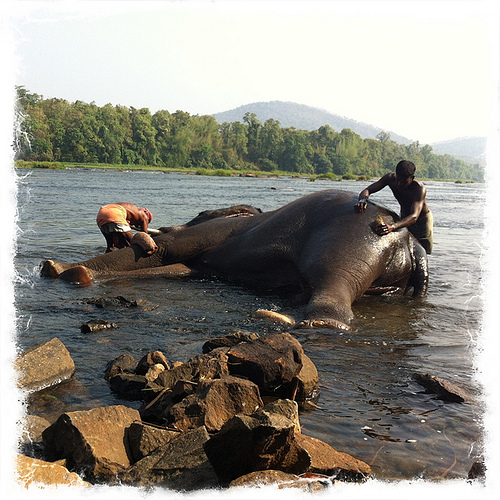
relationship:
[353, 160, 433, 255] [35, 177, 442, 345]
man washing elephant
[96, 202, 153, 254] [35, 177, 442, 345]
man washing elephant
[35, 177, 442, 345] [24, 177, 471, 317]
elephant in water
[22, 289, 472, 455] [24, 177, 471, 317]
rocks in water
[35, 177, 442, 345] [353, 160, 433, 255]
elephant by man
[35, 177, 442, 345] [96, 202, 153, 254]
elephant by man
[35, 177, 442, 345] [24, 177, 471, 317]
elephant laying in water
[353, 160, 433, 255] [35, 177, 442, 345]
man bathing elephant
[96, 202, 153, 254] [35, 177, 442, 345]
man bathing elephant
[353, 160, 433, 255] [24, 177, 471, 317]
man in water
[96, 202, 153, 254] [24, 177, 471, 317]
man in water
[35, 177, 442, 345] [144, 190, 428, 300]
elephant on side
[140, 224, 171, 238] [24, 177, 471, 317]
tusk out of water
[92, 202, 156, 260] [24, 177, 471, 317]
man bent in water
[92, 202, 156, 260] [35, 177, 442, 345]
man washing elephant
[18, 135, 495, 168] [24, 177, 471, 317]
shorline along water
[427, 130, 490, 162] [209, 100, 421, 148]
hill behind hill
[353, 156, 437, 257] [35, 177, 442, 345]
man washing elephant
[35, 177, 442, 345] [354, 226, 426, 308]
elephant has back side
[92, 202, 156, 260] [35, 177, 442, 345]
man cleaning elephant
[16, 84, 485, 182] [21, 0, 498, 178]
trees on other side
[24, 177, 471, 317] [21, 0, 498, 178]
water has other side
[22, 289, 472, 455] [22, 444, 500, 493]
rocks on river shore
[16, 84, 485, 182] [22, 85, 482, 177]
trees with leaves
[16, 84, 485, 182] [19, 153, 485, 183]
trees on shore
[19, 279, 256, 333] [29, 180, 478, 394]
ripples on surface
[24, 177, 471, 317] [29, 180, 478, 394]
water has surface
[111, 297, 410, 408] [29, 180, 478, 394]
spots on surface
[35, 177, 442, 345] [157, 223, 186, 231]
elephant has trunk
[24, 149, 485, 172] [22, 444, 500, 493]
grass on river shore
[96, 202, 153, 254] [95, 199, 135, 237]
man in clothing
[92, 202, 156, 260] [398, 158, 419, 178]
man with hair